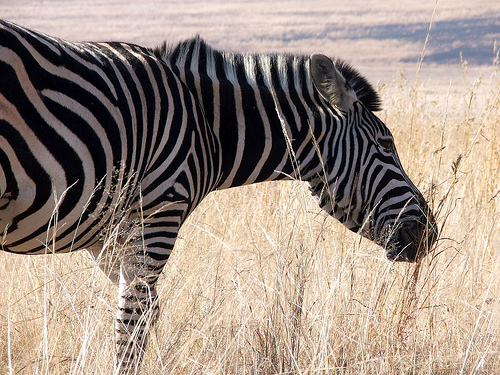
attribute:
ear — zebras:
[304, 48, 347, 111]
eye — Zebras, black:
[375, 133, 394, 150]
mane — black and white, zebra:
[159, 31, 383, 110]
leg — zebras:
[107, 201, 174, 371]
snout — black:
[388, 210, 437, 260]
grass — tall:
[248, 79, 476, 371]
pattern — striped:
[20, 50, 212, 190]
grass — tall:
[235, 182, 344, 372]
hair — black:
[331, 56, 381, 108]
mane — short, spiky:
[327, 53, 379, 111]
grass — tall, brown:
[0, 101, 496, 373]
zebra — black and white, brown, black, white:
[0, 21, 435, 372]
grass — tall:
[209, 62, 498, 345]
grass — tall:
[168, 60, 463, 373]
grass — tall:
[218, 81, 475, 372]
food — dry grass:
[243, 220, 463, 370]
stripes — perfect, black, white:
[19, 50, 290, 182]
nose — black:
[357, 183, 450, 304]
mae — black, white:
[121, 33, 395, 95]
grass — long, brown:
[248, 210, 498, 362]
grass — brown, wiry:
[216, 205, 466, 373]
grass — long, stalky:
[377, 57, 498, 335]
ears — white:
[259, 20, 378, 150]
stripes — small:
[86, 191, 198, 372]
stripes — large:
[4, 54, 148, 256]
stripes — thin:
[278, 111, 434, 206]